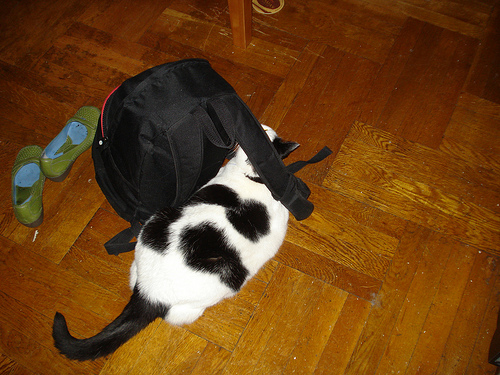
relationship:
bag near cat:
[123, 75, 219, 166] [65, 167, 257, 348]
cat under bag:
[65, 167, 257, 348] [123, 75, 219, 166]